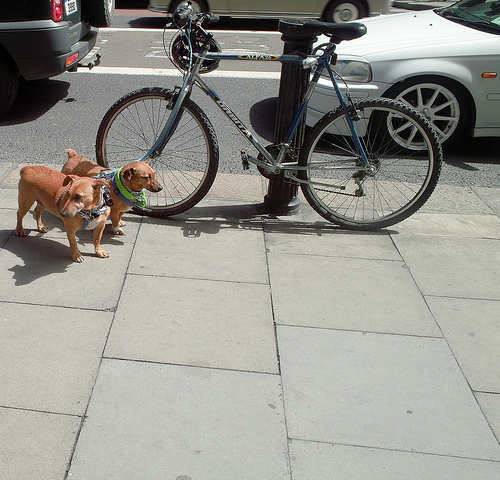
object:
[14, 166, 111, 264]
dog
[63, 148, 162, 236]
dog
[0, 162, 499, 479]
sidewalk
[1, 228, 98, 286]
shadow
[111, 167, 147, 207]
collar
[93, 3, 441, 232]
bike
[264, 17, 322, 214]
post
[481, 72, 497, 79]
reflector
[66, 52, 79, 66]
light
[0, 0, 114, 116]
car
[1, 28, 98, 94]
bottom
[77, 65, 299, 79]
line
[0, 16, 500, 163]
road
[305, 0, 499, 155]
car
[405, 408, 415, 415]
mark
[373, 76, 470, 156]
tire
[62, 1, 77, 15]
license plate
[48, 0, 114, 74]
back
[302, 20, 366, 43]
seat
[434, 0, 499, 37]
windshield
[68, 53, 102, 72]
tow hitch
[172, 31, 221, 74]
helmet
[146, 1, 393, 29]
car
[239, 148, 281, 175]
pedal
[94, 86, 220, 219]
tyre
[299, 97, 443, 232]
tyre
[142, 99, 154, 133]
spoke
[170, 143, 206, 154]
spoke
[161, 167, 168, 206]
spoke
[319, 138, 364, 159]
spoke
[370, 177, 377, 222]
spoke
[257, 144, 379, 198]
chain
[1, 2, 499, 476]
city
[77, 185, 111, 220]
collar